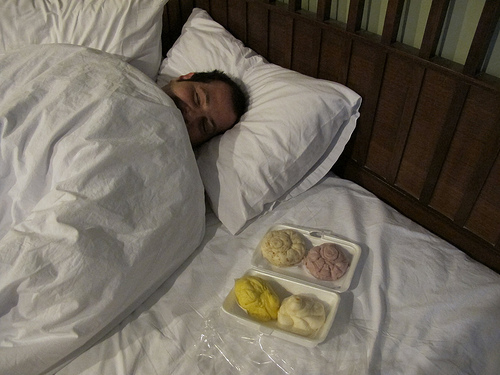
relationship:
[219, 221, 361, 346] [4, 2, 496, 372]
container on top of bed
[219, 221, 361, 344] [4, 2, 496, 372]
container on bed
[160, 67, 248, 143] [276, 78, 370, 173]
head on pillow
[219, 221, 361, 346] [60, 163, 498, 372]
container on bed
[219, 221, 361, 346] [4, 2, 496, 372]
container on top bed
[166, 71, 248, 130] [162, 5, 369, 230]
head on a pillow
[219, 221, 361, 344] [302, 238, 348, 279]
container with food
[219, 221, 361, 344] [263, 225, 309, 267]
container with food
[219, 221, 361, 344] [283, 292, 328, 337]
container with food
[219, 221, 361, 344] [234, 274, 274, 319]
container with food